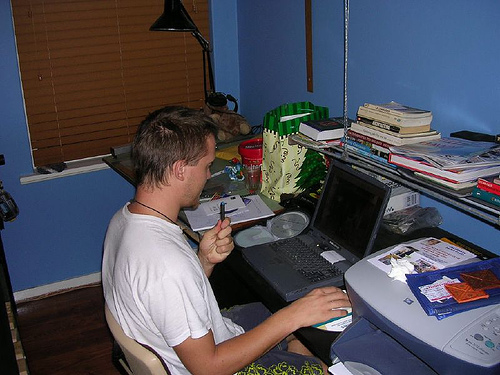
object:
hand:
[194, 216, 239, 266]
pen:
[215, 198, 230, 228]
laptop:
[233, 155, 400, 308]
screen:
[307, 164, 389, 263]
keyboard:
[265, 234, 349, 289]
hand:
[293, 282, 361, 328]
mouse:
[301, 282, 353, 326]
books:
[294, 96, 498, 207]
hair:
[122, 100, 226, 198]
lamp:
[145, 0, 246, 126]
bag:
[253, 98, 333, 205]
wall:
[373, 1, 500, 87]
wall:
[257, 0, 295, 93]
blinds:
[6, 1, 222, 175]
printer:
[319, 230, 499, 374]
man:
[83, 98, 358, 374]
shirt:
[90, 198, 253, 374]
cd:
[267, 210, 309, 241]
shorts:
[217, 298, 325, 374]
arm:
[137, 267, 292, 374]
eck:
[125, 185, 185, 229]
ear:
[171, 158, 190, 183]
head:
[124, 101, 226, 216]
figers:
[215, 215, 231, 255]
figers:
[309, 282, 352, 325]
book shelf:
[283, 112, 498, 238]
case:
[232, 206, 312, 255]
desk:
[92, 119, 499, 373]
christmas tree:
[290, 142, 333, 201]